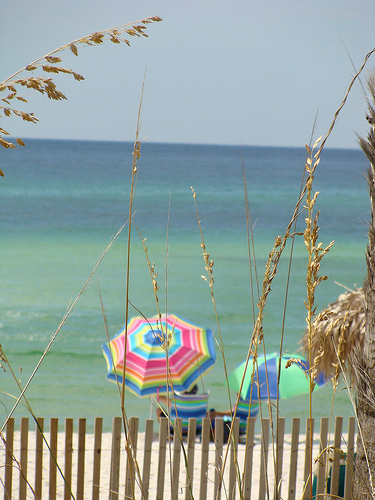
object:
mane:
[227, 397, 253, 440]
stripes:
[170, 392, 206, 406]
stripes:
[236, 401, 260, 412]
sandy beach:
[7, 416, 344, 495]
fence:
[0, 414, 367, 500]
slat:
[3, 415, 17, 497]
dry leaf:
[335, 307, 356, 330]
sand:
[100, 449, 109, 494]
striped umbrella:
[221, 351, 332, 400]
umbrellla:
[100, 313, 218, 396]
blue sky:
[0, 1, 372, 148]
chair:
[168, 383, 212, 435]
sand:
[260, 421, 294, 452]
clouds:
[215, 40, 290, 111]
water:
[0, 135, 374, 431]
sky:
[0, 0, 372, 150]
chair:
[214, 390, 267, 443]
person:
[210, 388, 260, 439]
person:
[155, 381, 210, 440]